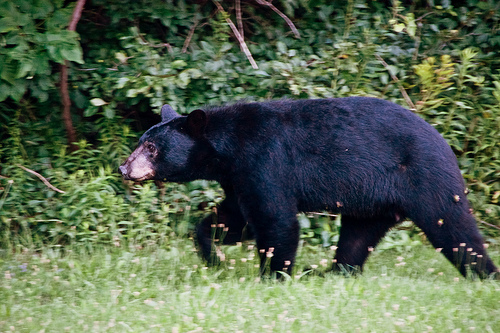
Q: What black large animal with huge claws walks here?
A: Bear.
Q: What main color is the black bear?
A: Black.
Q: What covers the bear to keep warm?
A: Fur.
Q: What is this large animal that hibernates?
A: Bear.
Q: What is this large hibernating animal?
A: Bear.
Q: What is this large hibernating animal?
A: Bear.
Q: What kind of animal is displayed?
A: Black bear.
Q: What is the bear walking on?
A: Grass.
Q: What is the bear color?
A: Black.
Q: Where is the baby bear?
A: Nowhere in sight.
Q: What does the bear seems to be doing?
A: Walking.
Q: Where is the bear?
A: In the grass.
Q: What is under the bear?
A: Grass.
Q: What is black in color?
A: The fur.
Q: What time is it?
A: Afternoon.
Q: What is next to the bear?
A: Trees.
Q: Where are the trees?
A: Next to the bear.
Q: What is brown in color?
A: Bear's face.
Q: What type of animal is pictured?
A: A black bear.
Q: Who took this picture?
A: A tourist.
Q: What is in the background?
A: Trees.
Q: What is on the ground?
A: Grass.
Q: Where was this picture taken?
A: In the wild.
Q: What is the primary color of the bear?
A: Black.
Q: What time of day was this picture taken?
A: Evening.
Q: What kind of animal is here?
A: A bear.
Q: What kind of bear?
A: A black bear.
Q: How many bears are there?
A: One.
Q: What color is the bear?
A: Black.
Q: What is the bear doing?
A: Walking.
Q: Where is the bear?
A: In a field.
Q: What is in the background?
A: Trees.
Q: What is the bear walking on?
A: Grass.